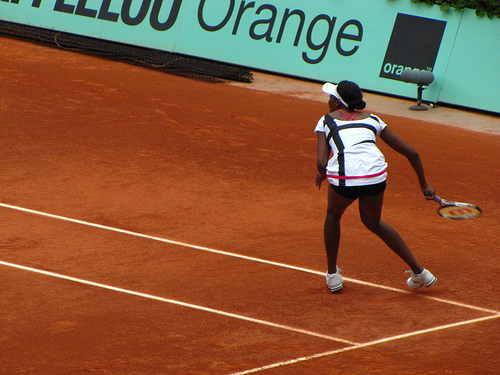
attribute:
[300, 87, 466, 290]
woman — playing, black, fit, strong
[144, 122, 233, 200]
court — orange, clay, dark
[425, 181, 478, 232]
racket — small, wilson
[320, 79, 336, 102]
hat — white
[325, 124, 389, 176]
outfit — white, black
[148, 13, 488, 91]
sign — blue